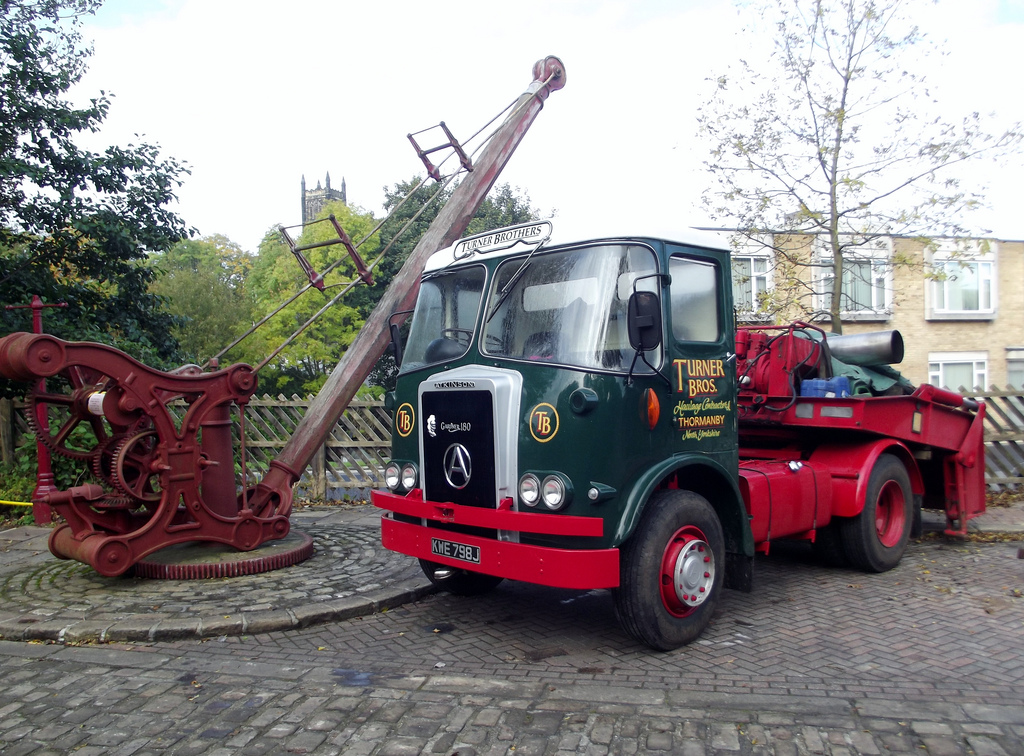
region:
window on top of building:
[819, 232, 896, 313]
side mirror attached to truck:
[620, 263, 679, 390]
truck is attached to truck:
[623, 480, 740, 652]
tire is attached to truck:
[857, 452, 916, 567]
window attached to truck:
[667, 251, 726, 349]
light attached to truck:
[537, 472, 580, 514]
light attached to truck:
[512, 472, 538, 508]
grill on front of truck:
[417, 377, 500, 511]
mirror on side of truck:
[621, 280, 660, 376]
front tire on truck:
[623, 489, 742, 655]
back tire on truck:
[836, 448, 953, 594]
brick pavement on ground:
[792, 593, 1005, 724]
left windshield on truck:
[498, 254, 615, 381]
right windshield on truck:
[394, 262, 493, 374]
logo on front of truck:
[438, 434, 473, 498]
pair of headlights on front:
[521, 475, 563, 518]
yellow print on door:
[672, 353, 733, 402]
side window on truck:
[673, 249, 719, 352]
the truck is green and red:
[411, 250, 984, 596]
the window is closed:
[909, 244, 1009, 322]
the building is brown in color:
[893, 237, 935, 354]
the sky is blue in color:
[192, 104, 275, 184]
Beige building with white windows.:
[691, 222, 1021, 447]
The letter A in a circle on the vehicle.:
[434, 443, 477, 488]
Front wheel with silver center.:
[618, 490, 740, 650]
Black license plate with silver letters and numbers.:
[428, 531, 480, 570]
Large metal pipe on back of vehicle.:
[782, 318, 904, 363]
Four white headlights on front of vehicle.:
[378, 461, 574, 506]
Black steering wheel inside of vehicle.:
[435, 318, 509, 356]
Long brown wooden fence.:
[4, 385, 1022, 525]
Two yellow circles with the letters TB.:
[383, 397, 562, 443]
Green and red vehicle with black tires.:
[368, 212, 995, 646]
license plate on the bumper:
[416, 531, 475, 567]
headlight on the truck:
[512, 465, 574, 511]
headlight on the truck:
[373, 461, 422, 497]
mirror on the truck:
[616, 287, 664, 365]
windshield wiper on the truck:
[473, 239, 565, 312]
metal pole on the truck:
[780, 322, 924, 362]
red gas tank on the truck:
[733, 437, 836, 549]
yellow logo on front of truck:
[520, 391, 568, 450]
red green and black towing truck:
[320, 200, 992, 624]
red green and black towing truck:
[311, 199, 1008, 651]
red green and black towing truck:
[334, 198, 1005, 661]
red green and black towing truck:
[339, 200, 1014, 654]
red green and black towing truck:
[336, 208, 1003, 660]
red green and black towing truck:
[332, 206, 999, 662]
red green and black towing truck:
[343, 206, 998, 656]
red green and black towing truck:
[327, 203, 992, 656]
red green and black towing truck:
[329, 221, 1006, 665]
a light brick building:
[714, 212, 1022, 429]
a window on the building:
[928, 247, 998, 315]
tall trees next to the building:
[25, 67, 396, 371]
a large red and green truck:
[384, 224, 939, 607]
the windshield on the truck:
[407, 269, 664, 367]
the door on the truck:
[660, 252, 737, 452]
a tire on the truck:
[644, 524, 736, 630]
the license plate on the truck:
[430, 534, 478, 564]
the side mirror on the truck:
[629, 288, 656, 343]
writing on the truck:
[672, 354, 731, 438]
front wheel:
[629, 499, 741, 659]